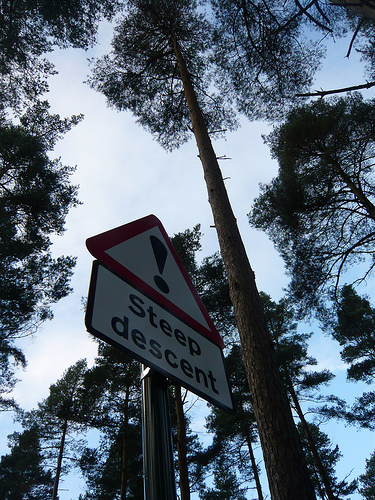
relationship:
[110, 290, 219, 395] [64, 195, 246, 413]
words on sign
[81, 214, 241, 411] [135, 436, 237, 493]
sign in ground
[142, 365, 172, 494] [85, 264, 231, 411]
post with two sign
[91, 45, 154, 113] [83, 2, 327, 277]
branch on tree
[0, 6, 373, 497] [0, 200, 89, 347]
sky above tree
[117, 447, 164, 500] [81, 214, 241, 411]
bottom of sign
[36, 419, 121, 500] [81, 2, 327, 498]
leaves on tree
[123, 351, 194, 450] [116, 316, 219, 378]
sign that says "steep descent"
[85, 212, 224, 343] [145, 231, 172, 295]
sign with a punctuation mark